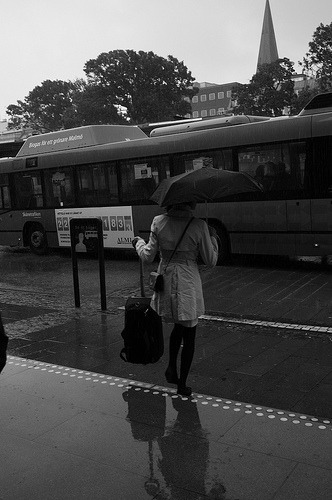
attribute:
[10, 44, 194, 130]
tree — large, full-leaved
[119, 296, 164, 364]
bag — black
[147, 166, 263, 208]
umbrella — black, large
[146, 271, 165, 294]
purse — black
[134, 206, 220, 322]
coat — winkled, colored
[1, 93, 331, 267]
bus — large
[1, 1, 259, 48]
sky — cloudy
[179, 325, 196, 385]
stocking — black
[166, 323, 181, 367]
stocking — black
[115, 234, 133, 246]
writing — black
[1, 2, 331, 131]
day — rainy, white, black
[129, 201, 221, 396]
woman — standing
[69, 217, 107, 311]
sign — black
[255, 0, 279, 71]
steeple — tall, pyramidal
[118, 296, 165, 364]
luggage — black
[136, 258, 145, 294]
handle — extended, black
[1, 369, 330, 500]
sidewalk — wet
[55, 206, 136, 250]
advertisement — print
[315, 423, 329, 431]
stone — circular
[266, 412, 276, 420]
stone — circular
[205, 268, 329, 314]
tiles — black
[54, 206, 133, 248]
sign — large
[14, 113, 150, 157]
hump — large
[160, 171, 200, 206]
spine — large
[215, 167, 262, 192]
spine — large